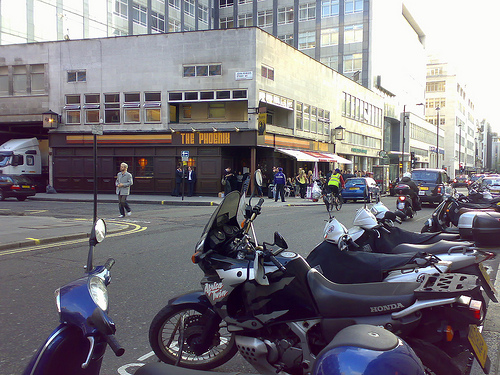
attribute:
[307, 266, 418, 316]
seat — leather, black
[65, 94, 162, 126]
windows — row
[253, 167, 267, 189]
mirror — rearview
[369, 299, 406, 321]
logo — honda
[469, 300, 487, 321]
reflector — red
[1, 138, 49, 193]
truck — semi, white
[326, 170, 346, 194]
person — riding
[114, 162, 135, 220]
man — walking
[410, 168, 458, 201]
car — black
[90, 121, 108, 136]
sign — white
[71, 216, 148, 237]
line — yellow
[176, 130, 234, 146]
letters — yellow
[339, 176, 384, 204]
car — blue